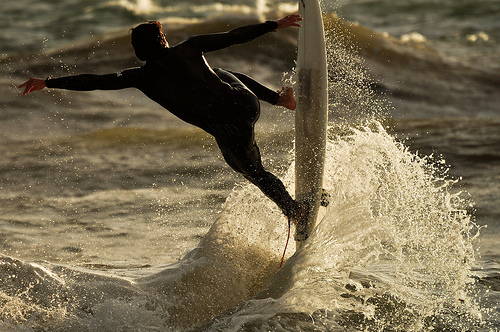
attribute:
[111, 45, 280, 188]
wetsuit — black, dark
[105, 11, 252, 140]
surfer — surfing, falling, here, trying, wearing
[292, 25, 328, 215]
surfboard — white, vertical, lifted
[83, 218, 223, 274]
water — splashing, spraying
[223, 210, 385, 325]
wave — lifted, white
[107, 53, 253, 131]
man — balancing, bare foot, here, surfing, airborn, vertical, wearing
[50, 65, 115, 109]
arm — extended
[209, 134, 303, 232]
leg — crouched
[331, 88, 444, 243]
seaspray — white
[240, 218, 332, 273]
tethercord — red